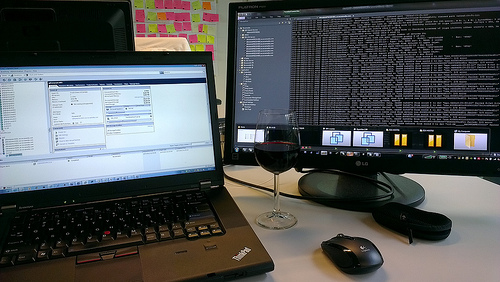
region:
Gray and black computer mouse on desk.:
[311, 229, 398, 274]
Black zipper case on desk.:
[373, 202, 474, 264]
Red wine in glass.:
[252, 133, 304, 188]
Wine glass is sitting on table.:
[248, 148, 296, 235]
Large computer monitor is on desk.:
[234, 40, 464, 183]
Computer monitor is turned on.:
[250, 60, 435, 119]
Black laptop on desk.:
[61, 86, 254, 262]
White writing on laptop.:
[224, 238, 264, 261]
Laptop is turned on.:
[64, 48, 244, 233]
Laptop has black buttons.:
[48, 199, 193, 243]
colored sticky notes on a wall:
[115, 0, 239, 82]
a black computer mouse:
[288, 211, 411, 278]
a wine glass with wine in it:
[231, 108, 328, 277]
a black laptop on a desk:
[2, 40, 244, 279]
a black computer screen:
[216, 18, 492, 203]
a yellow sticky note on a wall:
[128, 6, 170, 38]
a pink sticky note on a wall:
[148, 16, 213, 34]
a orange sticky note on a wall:
[124, 3, 180, 33]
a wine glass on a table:
[236, 108, 356, 273]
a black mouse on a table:
[304, 214, 377, 280]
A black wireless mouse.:
[316, 230, 386, 275]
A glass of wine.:
[253, 109, 307, 230]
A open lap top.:
[0, 49, 276, 280]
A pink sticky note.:
[133, 21, 148, 34]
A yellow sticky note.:
[145, 8, 159, 22]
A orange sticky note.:
[201, 0, 211, 10]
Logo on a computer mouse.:
[354, 240, 373, 252]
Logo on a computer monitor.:
[351, 155, 373, 170]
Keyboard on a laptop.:
[0, 188, 229, 270]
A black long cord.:
[213, 158, 397, 203]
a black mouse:
[314, 230, 389, 268]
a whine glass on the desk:
[251, 113, 306, 233]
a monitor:
[235, 13, 492, 99]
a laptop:
[0, 60, 220, 260]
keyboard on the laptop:
[21, 212, 181, 237]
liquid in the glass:
[256, 142, 293, 162]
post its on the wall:
[135, 5, 195, 32]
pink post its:
[135, 8, 145, 33]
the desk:
[407, 245, 469, 278]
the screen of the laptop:
[0, 70, 215, 170]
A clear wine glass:
[251, 107, 302, 229]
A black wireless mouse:
[318, 232, 383, 272]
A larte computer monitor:
[222, 0, 499, 209]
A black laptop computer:
[0, 50, 275, 280]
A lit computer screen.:
[0, 61, 217, 194]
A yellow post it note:
[145, 10, 156, 20]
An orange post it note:
[155, 10, 165, 20]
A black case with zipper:
[370, 197, 451, 242]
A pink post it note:
[183, 20, 193, 30]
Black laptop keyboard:
[0, 187, 226, 274]